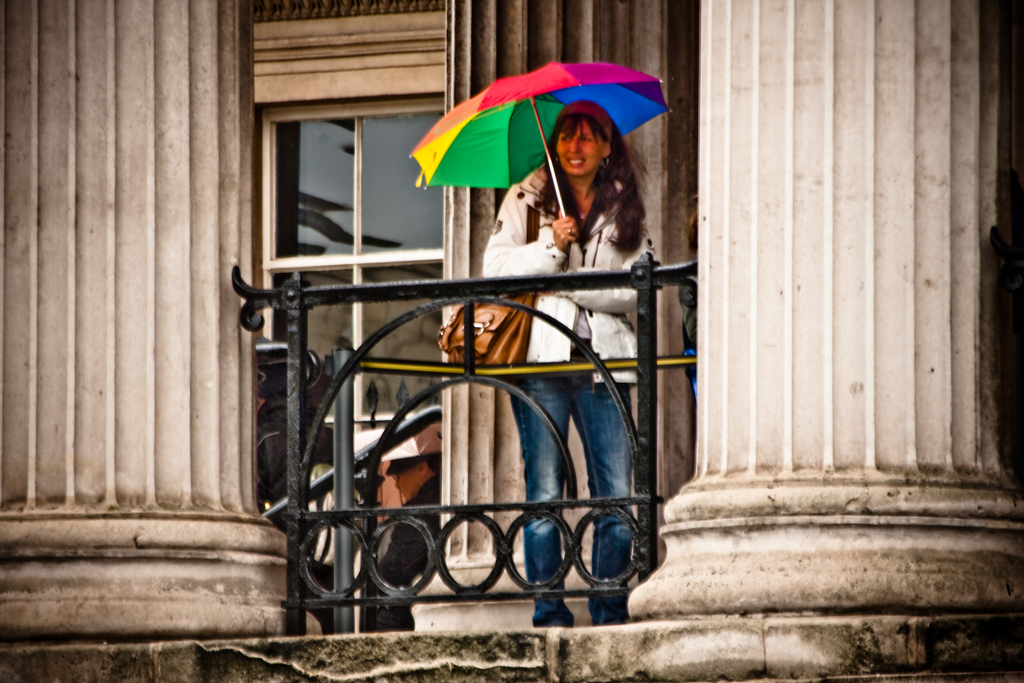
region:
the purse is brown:
[471, 303, 520, 354]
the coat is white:
[514, 206, 610, 296]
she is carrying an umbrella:
[499, 63, 604, 276]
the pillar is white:
[789, 253, 901, 437]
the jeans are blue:
[521, 414, 561, 500]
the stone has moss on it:
[910, 606, 1006, 667]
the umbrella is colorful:
[433, 60, 648, 187]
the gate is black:
[373, 268, 576, 605]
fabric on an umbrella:
[404, 42, 676, 197]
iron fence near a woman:
[220, 243, 730, 630]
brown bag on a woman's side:
[423, 277, 544, 375]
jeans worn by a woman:
[506, 354, 650, 620]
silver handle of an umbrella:
[527, 100, 567, 230]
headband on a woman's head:
[553, 97, 624, 154]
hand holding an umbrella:
[544, 209, 582, 254]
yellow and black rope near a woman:
[347, 347, 714, 386]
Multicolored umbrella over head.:
[413, 60, 680, 237]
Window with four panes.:
[265, 89, 443, 437]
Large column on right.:
[657, 7, 1011, 617]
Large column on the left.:
[3, 0, 286, 639]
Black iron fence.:
[229, 251, 689, 632]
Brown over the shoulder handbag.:
[435, 194, 560, 368]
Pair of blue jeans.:
[518, 352, 630, 627]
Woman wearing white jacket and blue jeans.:
[445, 92, 648, 627]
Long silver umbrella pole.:
[528, 103, 592, 256]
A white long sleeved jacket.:
[485, 182, 642, 379]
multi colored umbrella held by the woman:
[406, 47, 688, 203]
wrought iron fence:
[216, 239, 707, 623]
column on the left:
[687, 4, 1017, 652]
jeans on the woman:
[487, 329, 649, 611]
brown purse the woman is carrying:
[412, 262, 555, 380]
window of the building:
[247, 89, 459, 565]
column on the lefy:
[4, 6, 284, 618]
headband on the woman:
[564, 100, 626, 140]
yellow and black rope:
[336, 334, 700, 408]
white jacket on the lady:
[485, 161, 667, 393]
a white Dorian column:
[623, 0, 1022, 608]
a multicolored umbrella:
[408, 58, 669, 211]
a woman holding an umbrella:
[415, 58, 660, 618]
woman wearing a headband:
[479, 96, 661, 615]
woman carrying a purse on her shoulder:
[440, 100, 685, 620]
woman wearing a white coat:
[484, 99, 656, 621]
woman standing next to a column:
[482, 1, 1021, 616]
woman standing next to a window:
[253, 24, 659, 626]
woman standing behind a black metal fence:
[232, 102, 697, 621]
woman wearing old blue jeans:
[482, 96, 657, 618]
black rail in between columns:
[224, 246, 709, 643]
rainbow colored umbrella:
[405, 56, 663, 193]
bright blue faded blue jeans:
[515, 372, 651, 622]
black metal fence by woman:
[237, 269, 664, 634]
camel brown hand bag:
[445, 297, 523, 364]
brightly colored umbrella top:
[401, 54, 674, 194]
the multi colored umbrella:
[402, 52, 682, 234]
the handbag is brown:
[415, 195, 548, 368]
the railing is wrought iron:
[222, 256, 687, 617]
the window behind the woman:
[247, 92, 431, 454]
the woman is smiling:
[466, 99, 640, 618]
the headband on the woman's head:
[554, 95, 612, 134]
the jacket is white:
[479, 165, 642, 378]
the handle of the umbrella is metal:
[522, 95, 567, 244]